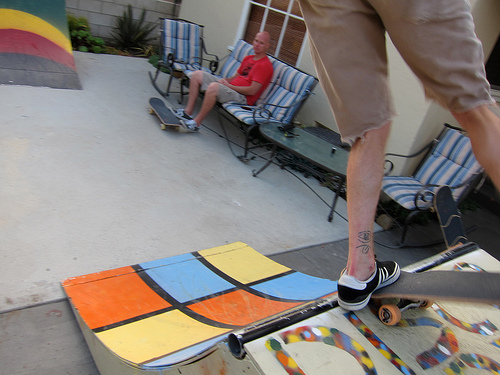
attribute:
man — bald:
[167, 21, 277, 133]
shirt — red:
[224, 53, 275, 112]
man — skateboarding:
[295, 0, 498, 313]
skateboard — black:
[422, 182, 475, 249]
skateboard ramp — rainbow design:
[1, 1, 86, 94]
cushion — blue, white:
[381, 126, 483, 211]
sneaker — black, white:
[332, 256, 401, 309]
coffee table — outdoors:
[252, 118, 396, 222]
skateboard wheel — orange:
[371, 303, 406, 327]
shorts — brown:
[295, 0, 499, 148]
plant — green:
[107, 4, 158, 57]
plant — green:
[66, 12, 110, 58]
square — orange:
[57, 264, 173, 333]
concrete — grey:
[0, 45, 386, 312]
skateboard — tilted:
[371, 260, 499, 323]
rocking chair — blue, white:
[144, 15, 221, 98]